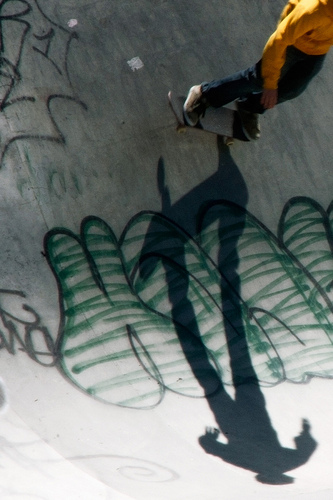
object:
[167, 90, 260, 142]
skateboard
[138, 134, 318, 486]
shadow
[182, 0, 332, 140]
person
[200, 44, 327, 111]
pants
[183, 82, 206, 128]
feet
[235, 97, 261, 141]
feet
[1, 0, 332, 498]
ramp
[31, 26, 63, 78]
graffite